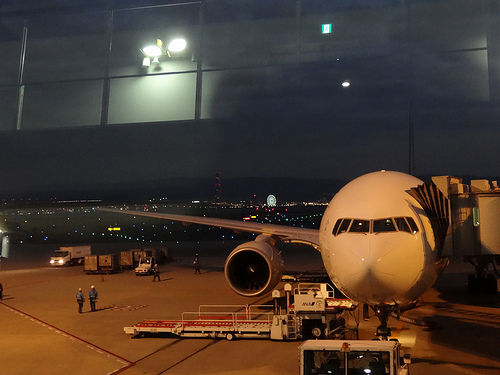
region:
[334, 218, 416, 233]
The cockpit windows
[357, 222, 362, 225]
Reflection on cockpit window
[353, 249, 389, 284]
The nose of the plane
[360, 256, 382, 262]
Reflection on the nose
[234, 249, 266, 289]
The engine of the jet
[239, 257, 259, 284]
Inside the engine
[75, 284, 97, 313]
Two people standing on the ground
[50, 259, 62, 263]
The lights of a truck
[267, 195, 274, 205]
A circular shiny object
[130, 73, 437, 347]
a plane on the ground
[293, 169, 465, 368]
an airplane on the ground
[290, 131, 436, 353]
a white plane on the ground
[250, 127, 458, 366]
a white airplane on the ground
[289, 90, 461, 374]
a large plane on the ground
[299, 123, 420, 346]
a large airplane on the ground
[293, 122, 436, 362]
a passenger plane on the ground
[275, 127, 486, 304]
a large white plane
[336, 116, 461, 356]
a large passenger plane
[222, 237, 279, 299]
front engine of plane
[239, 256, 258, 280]
turbines inside engine of plane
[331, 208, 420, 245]
front windows on plane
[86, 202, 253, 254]
side wing of plane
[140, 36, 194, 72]
two lights shining down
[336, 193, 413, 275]
cockpit of plane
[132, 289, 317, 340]
large long vehicle on tarmac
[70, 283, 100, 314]
two workers standing on tarmac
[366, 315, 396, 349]
wheel on front of plane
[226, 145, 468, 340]
the plane is parked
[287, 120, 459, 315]
the plane is white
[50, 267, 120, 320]
two men are standing together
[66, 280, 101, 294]
the men are wearing helmets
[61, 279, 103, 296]
the helmets are white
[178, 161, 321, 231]
lights in the background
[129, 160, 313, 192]
mountains in the distance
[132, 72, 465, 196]
the sky is overcast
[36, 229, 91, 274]
a white truck is in motion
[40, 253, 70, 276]
the headlights are on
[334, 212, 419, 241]
window of a plane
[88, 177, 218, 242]
wing of a plane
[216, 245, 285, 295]
turbine of a plane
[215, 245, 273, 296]
engine of a plane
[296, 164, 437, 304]
front of a plane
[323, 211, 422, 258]
cockpit of a plane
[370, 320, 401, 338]
wheel of a plane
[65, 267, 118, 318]
person on a ground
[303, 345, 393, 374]
window of a vehicle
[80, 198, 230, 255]
wingspan of a plane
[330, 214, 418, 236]
the cockpit windshield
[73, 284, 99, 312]
two workers have a conversation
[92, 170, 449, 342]
a large white airplane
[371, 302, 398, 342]
airplane landing gear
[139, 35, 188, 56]
two lit spot lights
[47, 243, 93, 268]
moving delivery truck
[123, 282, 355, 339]
movable steps for disembarking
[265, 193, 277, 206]
lit up ferris wheel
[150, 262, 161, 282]
a person walking across tarmac